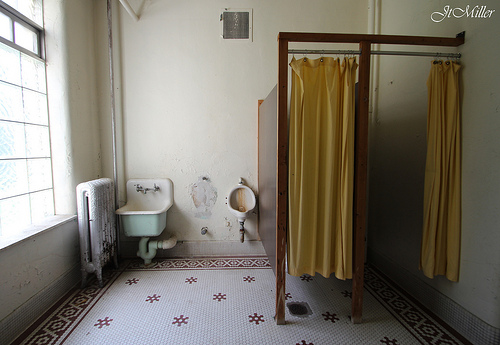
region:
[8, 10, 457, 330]
an old bathroom with a missing tiolet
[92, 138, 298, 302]
this bathroom has no toliet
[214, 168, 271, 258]
a urinal on the wall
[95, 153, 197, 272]
a sink on the wall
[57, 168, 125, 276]
radiator in the bathroom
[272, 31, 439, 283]
a curtain on a stall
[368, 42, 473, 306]
an open curtain on the stall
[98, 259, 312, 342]
a flower print tile floor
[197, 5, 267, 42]
a vent on the wall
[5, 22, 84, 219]
a window in the bathroom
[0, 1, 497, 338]
white walls of bathroom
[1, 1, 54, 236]
light shining through window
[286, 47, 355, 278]
curtain hanging from rod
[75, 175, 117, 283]
radiator in corner of room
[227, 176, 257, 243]
urinal with rust inside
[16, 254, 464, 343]
tiled floor with pattern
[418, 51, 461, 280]
open curtain next to wall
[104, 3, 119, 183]
long metal silver pole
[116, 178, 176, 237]
white sink on wall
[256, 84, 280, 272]
wood wall of stall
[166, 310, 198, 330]
design on floor tile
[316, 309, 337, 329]
design on floor tile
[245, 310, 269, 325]
design on floor tile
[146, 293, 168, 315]
design on floor tile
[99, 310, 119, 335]
design on floor tile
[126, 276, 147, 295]
design on floor tile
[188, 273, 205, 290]
design on floor tile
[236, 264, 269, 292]
design on floor tile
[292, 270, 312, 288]
design on floor tile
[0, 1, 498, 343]
a small bathroom area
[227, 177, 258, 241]
a urinal in a bathroom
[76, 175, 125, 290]
a rusty radiator heater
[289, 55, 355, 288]
a yellow shower curtain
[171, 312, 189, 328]
a flower design on a floor tile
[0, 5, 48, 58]
a small window in a bathroom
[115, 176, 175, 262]
a sink in a small bathroom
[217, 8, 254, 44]
a heat vent in the wall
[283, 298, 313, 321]
a drain in the floor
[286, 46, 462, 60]
a metal curtain rod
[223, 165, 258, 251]
Urinal in the bathroom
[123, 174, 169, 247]
sink in the bathroom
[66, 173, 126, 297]
radiator in the bathroom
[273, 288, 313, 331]
drain on the floor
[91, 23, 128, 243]
silver pole in the room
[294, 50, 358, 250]
curtain hanging up in the room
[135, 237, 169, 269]
drain pipe on the wall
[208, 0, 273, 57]
vent on the wall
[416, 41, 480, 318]
yellow shower curtain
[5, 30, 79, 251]
white window frame